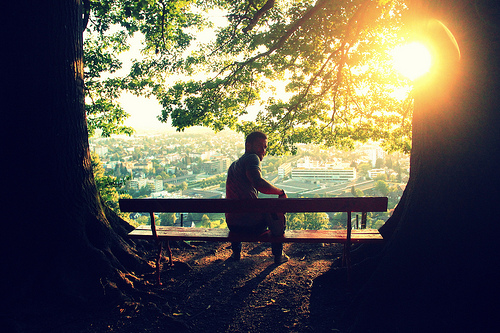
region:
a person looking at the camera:
[218, 120, 322, 262]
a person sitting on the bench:
[119, 117, 383, 262]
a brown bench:
[105, 183, 410, 265]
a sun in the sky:
[369, 24, 486, 94]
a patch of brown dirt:
[120, 224, 375, 328]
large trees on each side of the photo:
[1, 2, 493, 321]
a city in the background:
[85, 117, 412, 249]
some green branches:
[85, 7, 415, 151]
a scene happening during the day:
[5, 10, 488, 331]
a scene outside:
[10, 3, 498, 327]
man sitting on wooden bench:
[225, 118, 297, 268]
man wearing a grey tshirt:
[217, 122, 301, 278]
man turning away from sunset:
[217, 122, 294, 270]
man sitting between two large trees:
[205, 122, 305, 267]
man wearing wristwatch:
[214, 122, 300, 271]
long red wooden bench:
[108, 185, 393, 272]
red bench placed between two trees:
[113, 192, 403, 273]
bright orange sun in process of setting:
[364, 14, 469, 121]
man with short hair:
[217, 124, 291, 271]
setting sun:
[357, 10, 477, 127]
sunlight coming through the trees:
[346, 20, 470, 105]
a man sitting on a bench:
[190, 115, 321, 296]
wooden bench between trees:
[97, 181, 440, 264]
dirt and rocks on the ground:
[184, 272, 291, 332]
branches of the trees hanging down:
[172, 8, 433, 166]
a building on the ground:
[277, 152, 376, 207]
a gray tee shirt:
[210, 152, 286, 232]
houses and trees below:
[102, 133, 227, 222]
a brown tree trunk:
[0, 30, 172, 282]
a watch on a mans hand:
[268, 183, 300, 204]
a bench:
[130, 188, 222, 262]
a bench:
[130, 160, 260, 290]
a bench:
[100, 175, 215, 287]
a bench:
[100, 127, 240, 231]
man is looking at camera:
[207, 114, 314, 288]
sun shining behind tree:
[371, 13, 476, 128]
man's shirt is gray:
[217, 145, 268, 215]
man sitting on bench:
[96, 120, 388, 305]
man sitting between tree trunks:
[81, 77, 386, 267]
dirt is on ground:
[140, 225, 345, 320]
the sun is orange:
[380, 30, 445, 107]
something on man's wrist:
[265, 175, 290, 205]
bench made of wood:
[99, 156, 403, 258]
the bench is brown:
[75, 161, 420, 246]